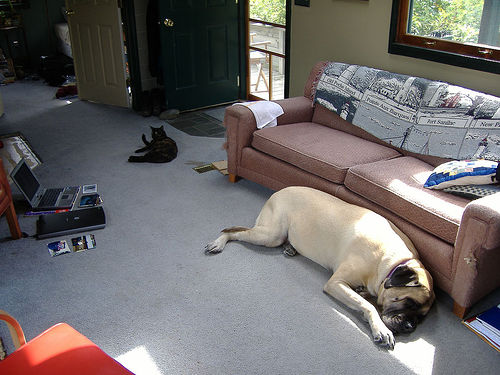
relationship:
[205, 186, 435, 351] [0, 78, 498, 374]
dog sleeping on carpet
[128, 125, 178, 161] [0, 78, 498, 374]
cat on carpet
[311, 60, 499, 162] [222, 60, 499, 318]
throw on couch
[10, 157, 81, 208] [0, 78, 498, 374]
laptop on carpet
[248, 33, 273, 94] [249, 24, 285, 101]
chair on balcony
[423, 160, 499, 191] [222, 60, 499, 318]
pillow on couch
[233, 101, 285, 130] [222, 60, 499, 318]
towel on couch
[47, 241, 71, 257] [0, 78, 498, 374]
photo on carpet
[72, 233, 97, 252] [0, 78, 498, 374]
photo on carpet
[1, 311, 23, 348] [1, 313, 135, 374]
arm on chair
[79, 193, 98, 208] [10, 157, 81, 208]
cd case in front of laptop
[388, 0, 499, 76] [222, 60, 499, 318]
window behind couch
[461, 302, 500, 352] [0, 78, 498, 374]
books are on carpet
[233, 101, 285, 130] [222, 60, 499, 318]
towel hanging from couch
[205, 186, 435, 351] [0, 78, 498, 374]
dog on carpet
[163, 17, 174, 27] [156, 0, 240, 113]
knob on door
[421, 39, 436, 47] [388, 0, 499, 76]
handle on window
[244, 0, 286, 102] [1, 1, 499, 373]
screen door to room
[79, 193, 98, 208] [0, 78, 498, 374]
cd case on carpet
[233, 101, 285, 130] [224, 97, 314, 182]
towel on arm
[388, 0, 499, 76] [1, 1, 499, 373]
window in room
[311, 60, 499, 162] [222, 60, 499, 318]
throw hanging on couch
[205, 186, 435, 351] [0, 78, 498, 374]
dog lying on carpet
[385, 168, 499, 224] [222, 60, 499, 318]
sunlight on couch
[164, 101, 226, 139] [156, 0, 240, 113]
tile near door